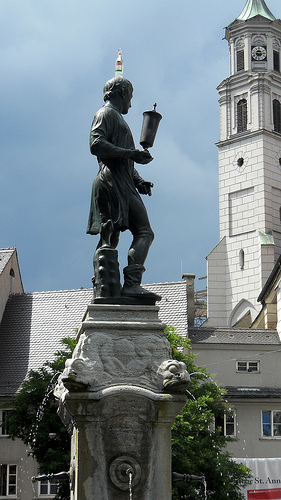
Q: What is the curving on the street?
A: Statue of a man.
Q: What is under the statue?
A: A fountain.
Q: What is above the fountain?
A: A statue.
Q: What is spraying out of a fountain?
A: Water.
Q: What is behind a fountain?
A: A tree.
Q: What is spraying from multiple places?
A: Water.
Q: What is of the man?
A: A dark statue.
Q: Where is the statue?
A: Top of pedestal;.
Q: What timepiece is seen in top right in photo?
A: Clock.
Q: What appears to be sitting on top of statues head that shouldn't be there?
A: Bottle.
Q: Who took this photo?
A: Photographer.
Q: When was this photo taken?
A: Daytime.